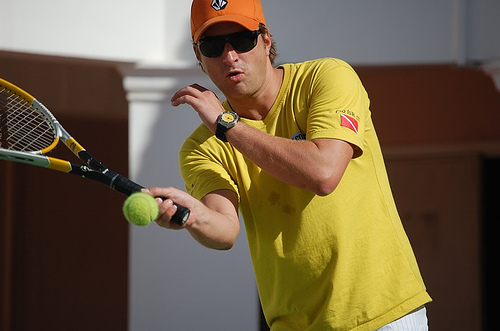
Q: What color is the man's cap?
A: Orange.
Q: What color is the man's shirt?
A: Yellow.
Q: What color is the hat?
A: Orange.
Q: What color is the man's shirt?
A: Yellow.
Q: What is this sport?
A: Tennis.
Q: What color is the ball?
A: Light green.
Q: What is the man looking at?
A: The ball.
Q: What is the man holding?
A: Tennis racket.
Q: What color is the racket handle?
A: Black.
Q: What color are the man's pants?
A: White.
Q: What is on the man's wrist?
A: Watch.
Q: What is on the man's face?
A: Sunglasses.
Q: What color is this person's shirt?
A: Yellow.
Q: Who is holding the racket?
A: The tennis player.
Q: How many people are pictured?
A: One.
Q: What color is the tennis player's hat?
A: Orange.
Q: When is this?
A: Daytime.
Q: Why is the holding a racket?
A: To hit the ball.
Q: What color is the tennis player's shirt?
A: Yellow.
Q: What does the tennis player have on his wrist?
A: A watch.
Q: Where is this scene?
A: A tennis court.